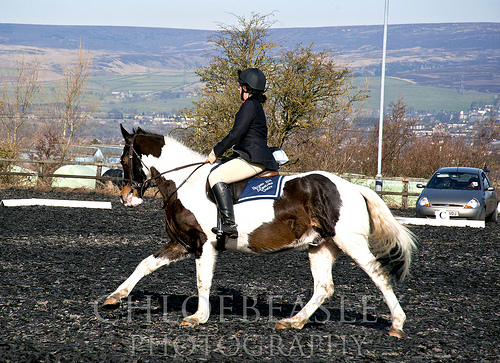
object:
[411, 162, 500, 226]
car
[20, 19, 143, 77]
background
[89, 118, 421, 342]
horse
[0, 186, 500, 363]
field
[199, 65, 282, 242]
person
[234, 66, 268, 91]
helmet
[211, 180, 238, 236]
boots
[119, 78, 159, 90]
grass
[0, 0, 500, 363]
day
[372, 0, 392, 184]
pole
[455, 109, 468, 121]
houses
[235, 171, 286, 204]
blue blanket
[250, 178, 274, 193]
white letters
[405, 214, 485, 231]
curb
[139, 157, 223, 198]
reign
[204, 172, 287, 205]
saddle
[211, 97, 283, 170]
jacket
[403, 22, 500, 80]
hill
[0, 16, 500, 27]
horizon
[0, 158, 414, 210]
fence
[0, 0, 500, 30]
sky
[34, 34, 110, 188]
tree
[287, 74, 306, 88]
leaves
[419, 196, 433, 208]
lights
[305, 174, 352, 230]
brown and white hair